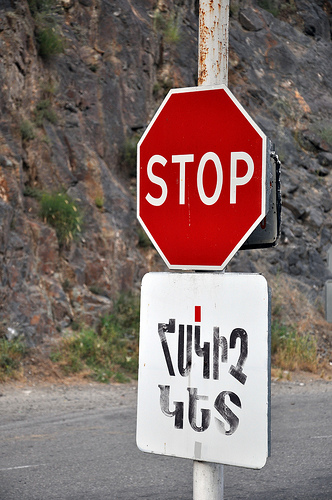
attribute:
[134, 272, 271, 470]
sign — red, octagon, white trimmed, white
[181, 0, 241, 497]
pole — white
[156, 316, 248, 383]
lettering — black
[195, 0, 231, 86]
pole — white, metal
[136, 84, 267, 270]
stop sign — red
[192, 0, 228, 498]
pole — rusted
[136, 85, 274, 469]
signs — rusted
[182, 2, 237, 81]
pole — rusted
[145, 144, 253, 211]
letters — white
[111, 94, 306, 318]
sign — red and white